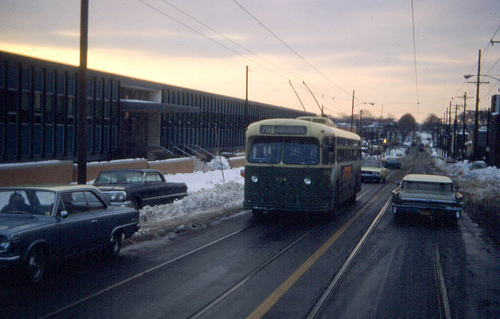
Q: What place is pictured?
A: It is a street.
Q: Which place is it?
A: It is a street.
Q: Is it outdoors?
A: Yes, it is outdoors.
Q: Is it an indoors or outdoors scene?
A: It is outdoors.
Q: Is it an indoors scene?
A: No, it is outdoors.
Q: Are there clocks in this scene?
A: No, there are no clocks.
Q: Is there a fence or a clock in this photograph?
A: No, there are no clocks or fences.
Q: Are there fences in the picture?
A: No, there are no fences.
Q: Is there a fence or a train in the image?
A: No, there are no fences or trains.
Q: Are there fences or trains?
A: No, there are no fences or trains.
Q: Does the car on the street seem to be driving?
A: Yes, the car is driving.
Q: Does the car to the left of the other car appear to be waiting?
A: No, the car is driving.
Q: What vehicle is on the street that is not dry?
A: The vehicle is a car.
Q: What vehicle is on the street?
A: The vehicle is a car.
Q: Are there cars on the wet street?
A: Yes, there is a car on the street.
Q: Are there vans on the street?
A: No, there is a car on the street.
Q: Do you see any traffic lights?
A: No, there are no traffic lights.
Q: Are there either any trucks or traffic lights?
A: No, there are no traffic lights or trucks.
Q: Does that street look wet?
A: Yes, the street is wet.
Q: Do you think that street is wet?
A: Yes, the street is wet.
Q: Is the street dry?
A: No, the street is wet.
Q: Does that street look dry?
A: No, the street is wet.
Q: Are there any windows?
A: Yes, there is a window.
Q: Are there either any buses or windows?
A: Yes, there is a window.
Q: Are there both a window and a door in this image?
A: No, there is a window but no doors.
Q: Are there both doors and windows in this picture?
A: No, there is a window but no doors.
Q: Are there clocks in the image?
A: No, there are no clocks.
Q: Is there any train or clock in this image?
A: No, there are no clocks or trains.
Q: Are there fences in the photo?
A: No, there are no fences.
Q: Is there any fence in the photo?
A: No, there are no fences.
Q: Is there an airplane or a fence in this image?
A: No, there are no fences or airplanes.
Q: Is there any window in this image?
A: Yes, there is a window.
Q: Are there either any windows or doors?
A: Yes, there is a window.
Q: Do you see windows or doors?
A: Yes, there is a window.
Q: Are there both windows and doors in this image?
A: No, there is a window but no doors.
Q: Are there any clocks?
A: No, there are no clocks.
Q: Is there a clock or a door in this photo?
A: No, there are no clocks or doors.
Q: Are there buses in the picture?
A: Yes, there is a bus.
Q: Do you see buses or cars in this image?
A: Yes, there is a bus.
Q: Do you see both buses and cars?
A: Yes, there are both a bus and a car.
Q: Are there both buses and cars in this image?
A: Yes, there are both a bus and a car.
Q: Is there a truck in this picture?
A: No, there are no trucks.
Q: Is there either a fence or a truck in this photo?
A: No, there are no trucks or fences.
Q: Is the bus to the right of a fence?
A: No, the bus is to the right of the car.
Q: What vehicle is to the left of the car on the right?
A: The vehicle is a bus.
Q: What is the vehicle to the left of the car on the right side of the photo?
A: The vehicle is a bus.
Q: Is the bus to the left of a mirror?
A: No, the bus is to the left of the car.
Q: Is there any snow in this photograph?
A: Yes, there is snow.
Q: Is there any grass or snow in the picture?
A: Yes, there is snow.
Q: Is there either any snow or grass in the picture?
A: Yes, there is snow.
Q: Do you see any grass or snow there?
A: Yes, there is snow.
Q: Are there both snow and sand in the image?
A: No, there is snow but no sand.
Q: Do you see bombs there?
A: No, there are no bombs.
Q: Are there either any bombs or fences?
A: No, there are no bombs or fences.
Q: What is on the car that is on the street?
A: The snow is on the car.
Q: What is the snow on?
A: The snow is on the car.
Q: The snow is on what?
A: The snow is on the car.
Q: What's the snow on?
A: The snow is on the car.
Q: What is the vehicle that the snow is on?
A: The vehicle is a car.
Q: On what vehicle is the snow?
A: The snow is on the car.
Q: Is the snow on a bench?
A: No, the snow is on the car.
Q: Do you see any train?
A: No, there are no trains.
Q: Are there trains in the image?
A: No, there are no trains.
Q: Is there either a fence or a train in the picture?
A: No, there are no trains or fences.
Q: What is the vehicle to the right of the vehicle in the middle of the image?
A: The vehicle is a car.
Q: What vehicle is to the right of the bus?
A: The vehicle is a car.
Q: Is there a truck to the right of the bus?
A: No, there is a car to the right of the bus.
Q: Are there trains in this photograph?
A: No, there are no trains.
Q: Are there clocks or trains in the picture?
A: No, there are no trains or clocks.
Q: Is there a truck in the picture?
A: No, there are no trucks.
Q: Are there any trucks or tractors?
A: No, there are no trucks or tractors.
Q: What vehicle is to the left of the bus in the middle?
A: The vehicle is a car.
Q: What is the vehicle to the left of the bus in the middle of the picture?
A: The vehicle is a car.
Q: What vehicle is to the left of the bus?
A: The vehicle is a car.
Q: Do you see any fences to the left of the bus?
A: No, there is a car to the left of the bus.